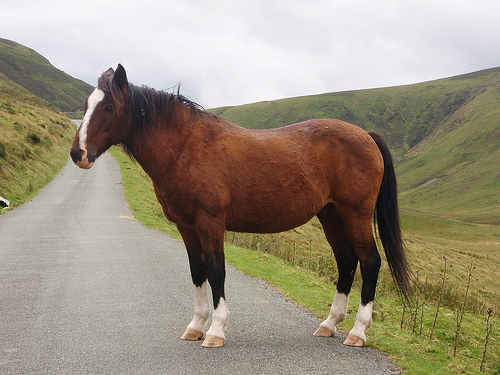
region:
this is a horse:
[62, 42, 395, 373]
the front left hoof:
[193, 322, 233, 352]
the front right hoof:
[152, 309, 231, 347]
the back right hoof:
[308, 314, 349, 346]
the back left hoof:
[333, 330, 385, 367]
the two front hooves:
[144, 297, 255, 360]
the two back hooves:
[307, 319, 387, 369]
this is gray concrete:
[76, 305, 126, 343]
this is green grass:
[440, 216, 458, 242]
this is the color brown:
[246, 203, 281, 225]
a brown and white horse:
[66, 74, 408, 351]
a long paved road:
[10, 109, 359, 372]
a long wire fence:
[199, 218, 496, 363]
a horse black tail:
[357, 125, 422, 309]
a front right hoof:
[182, 282, 209, 346]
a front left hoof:
[205, 293, 228, 350]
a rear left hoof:
[342, 297, 373, 349]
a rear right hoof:
[312, 284, 350, 338]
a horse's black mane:
[111, 73, 200, 143]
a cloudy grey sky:
[1, 1, 498, 98]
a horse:
[86, 67, 351, 325]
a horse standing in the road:
[69, 63, 412, 351]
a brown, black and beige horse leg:
[186, 198, 234, 349]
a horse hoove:
[200, 333, 228, 355]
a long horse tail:
[369, 129, 423, 314]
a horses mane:
[106, 70, 209, 147]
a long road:
[4, 118, 397, 373]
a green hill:
[223, 65, 498, 238]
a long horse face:
[69, 79, 114, 169]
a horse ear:
[111, 60, 126, 88]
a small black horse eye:
[103, 103, 117, 114]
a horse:
[158, 107, 432, 354]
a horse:
[177, 32, 354, 272]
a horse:
[274, 218, 384, 358]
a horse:
[215, 95, 329, 325]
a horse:
[331, 125, 359, 317]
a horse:
[194, 154, 302, 309]